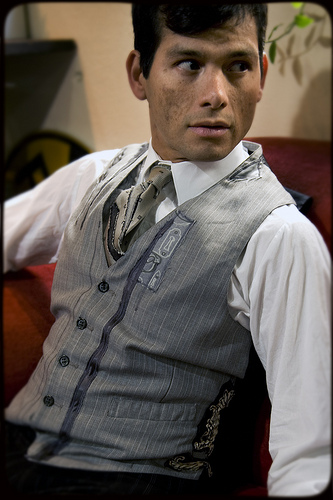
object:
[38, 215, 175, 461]
line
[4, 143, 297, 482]
vest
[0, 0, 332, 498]
man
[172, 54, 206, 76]
eyes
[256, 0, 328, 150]
right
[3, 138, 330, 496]
t shirt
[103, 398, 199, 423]
pocket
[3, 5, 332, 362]
room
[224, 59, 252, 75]
eyes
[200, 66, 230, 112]
nose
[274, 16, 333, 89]
shadow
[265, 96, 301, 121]
ground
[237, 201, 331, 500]
sleeve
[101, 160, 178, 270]
tie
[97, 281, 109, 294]
button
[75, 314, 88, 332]
button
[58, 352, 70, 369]
button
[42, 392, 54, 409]
button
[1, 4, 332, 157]
wall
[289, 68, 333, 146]
shadow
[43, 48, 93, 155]
shadow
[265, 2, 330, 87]
plant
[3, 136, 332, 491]
furniture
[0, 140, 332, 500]
shirt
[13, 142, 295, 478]
front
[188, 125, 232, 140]
lip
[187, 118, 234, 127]
lip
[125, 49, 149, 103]
ear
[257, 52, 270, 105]
ear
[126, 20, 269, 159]
skin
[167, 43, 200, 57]
brow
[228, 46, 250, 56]
brow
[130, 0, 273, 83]
hair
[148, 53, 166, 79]
sideburn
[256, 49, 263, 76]
sideburn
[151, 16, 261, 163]
face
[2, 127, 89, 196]
object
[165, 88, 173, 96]
blemish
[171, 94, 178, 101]
blemish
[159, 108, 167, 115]
blemish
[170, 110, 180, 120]
blemish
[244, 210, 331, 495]
sleeve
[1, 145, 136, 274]
sleeve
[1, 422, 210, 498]
pants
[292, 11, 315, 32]
leaves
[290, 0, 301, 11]
leaves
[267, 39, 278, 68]
leaves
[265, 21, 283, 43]
leaves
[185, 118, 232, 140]
mouth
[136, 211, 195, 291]
patch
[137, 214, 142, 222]
squares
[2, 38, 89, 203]
furniture